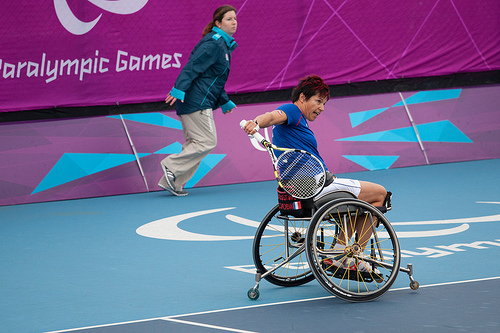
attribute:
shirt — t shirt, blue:
[225, 116, 305, 188]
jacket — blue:
[162, 22, 272, 101]